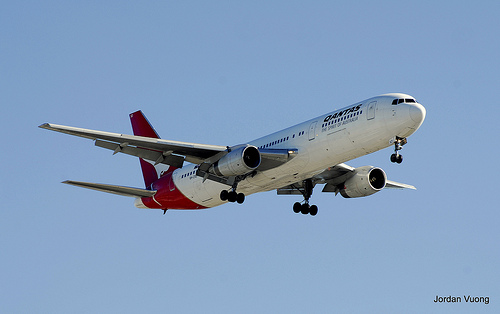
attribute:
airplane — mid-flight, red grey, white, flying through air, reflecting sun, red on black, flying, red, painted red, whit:
[38, 94, 426, 216]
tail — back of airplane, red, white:
[128, 108, 179, 187]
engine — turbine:
[206, 145, 261, 177]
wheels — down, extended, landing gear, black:
[219, 189, 244, 205]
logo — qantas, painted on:
[321, 103, 362, 123]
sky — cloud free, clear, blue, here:
[1, 0, 499, 313]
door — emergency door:
[168, 174, 176, 189]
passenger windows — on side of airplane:
[258, 135, 290, 148]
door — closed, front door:
[367, 100, 377, 120]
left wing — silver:
[35, 122, 298, 173]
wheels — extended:
[292, 202, 317, 216]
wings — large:
[39, 123, 416, 190]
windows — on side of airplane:
[179, 170, 194, 177]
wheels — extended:
[389, 152, 404, 163]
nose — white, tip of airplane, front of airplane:
[384, 93, 425, 141]